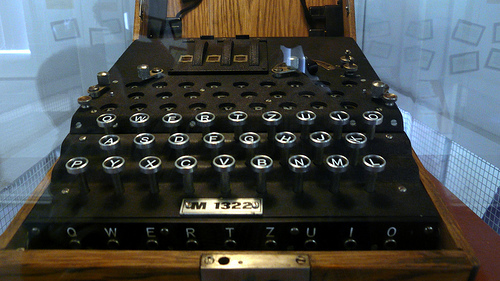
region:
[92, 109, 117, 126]
one round Q typewriter key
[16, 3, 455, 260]
one black teletype machine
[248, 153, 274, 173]
one rounded silver and black key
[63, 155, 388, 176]
several round metal keys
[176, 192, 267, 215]
one black and silver metal plate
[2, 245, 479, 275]
edge of brown wooden box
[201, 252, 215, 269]
one round metal screw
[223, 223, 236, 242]
one white capital T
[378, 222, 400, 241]
one white capital letter O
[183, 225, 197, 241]
one white capital letter R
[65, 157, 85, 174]
An alphabet letter on a fax machine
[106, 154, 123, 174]
An alphabet letter on a fax machine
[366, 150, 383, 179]
An alphabet letter on a fax machine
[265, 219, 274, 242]
An alphabet letter on a fax machine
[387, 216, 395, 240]
An alphabet letter on a fax machine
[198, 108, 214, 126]
An alphabet letter on a fax machine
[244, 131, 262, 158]
An alphabet letter on a fax machine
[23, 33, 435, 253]
black typewriter on desk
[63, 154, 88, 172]
Letter P key on typewriter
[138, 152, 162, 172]
Letter x key on typewriter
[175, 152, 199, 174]
letter c key on typewriter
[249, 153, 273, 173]
Letter B key on typewriter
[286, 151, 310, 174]
Letter N key on typewriter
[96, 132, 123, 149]
Letter A key on typewriter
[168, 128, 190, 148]
Letter D key on typewriter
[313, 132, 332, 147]
Letter J key on typewriter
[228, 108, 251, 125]
Letter T key on typewriter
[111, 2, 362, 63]
light brown cabinet with dark stripes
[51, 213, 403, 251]
letters at base of the machine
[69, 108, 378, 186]
letters on knobs on the machine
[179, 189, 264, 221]
a medal plate with black marking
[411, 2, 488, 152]
white curtain with blue boxes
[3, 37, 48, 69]
bright rays shinning through curtain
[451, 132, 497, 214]
wire screen opening on the wall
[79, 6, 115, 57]
small plaque on the wall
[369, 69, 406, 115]
silver knob on the machine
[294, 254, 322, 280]
screw in the machine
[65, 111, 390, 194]
letter keys on a keyboard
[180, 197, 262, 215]
numbers on the front of the board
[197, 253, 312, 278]
a screwed in metal plate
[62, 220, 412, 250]
words on the front of the board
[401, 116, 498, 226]
a metal grate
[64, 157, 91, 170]
the letter p on a key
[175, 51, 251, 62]
three yellow squares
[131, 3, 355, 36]
a wooden latch top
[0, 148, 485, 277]
a wooden box frame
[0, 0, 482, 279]
an antique typewriter